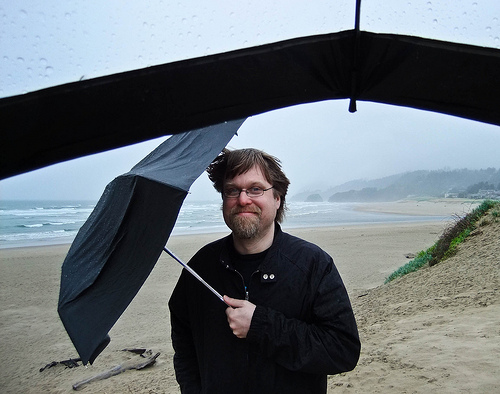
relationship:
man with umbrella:
[188, 154, 355, 393] [56, 120, 230, 355]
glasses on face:
[221, 182, 278, 200] [206, 144, 291, 236]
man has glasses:
[167, 147, 361, 393] [216, 180, 283, 202]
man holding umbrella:
[167, 147, 361, 393] [56, 114, 251, 365]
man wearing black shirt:
[167, 147, 361, 393] [170, 222, 365, 392]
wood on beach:
[72, 345, 161, 390] [2, 221, 499, 391]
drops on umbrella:
[0, 0, 495, 97] [0, 1, 499, 178]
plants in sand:
[382, 198, 492, 285] [371, 220, 499, 390]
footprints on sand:
[1, 223, 499, 392] [0, 200, 499, 392]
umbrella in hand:
[76, 147, 228, 234] [210, 280, 259, 340]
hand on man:
[210, 280, 259, 340] [188, 154, 355, 393]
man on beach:
[167, 147, 361, 393] [325, 209, 428, 247]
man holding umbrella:
[167, 147, 361, 393] [60, 100, 195, 337]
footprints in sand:
[365, 306, 447, 391] [374, 295, 480, 382]